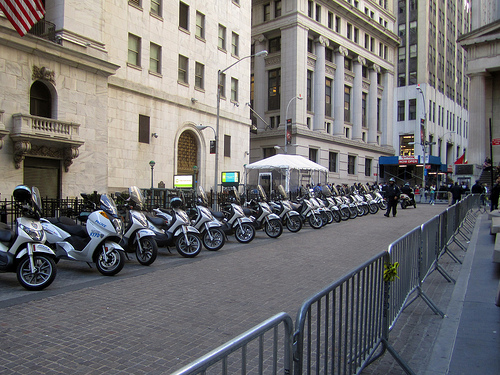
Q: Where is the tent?
A: Behind mopeds.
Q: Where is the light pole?
A: Behind the mopeds.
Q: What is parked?
A: Motorbikes.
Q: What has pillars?
A: Buildings.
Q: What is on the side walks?
A: Light posts.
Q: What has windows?
A: Buildings.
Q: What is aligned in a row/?
A: Motorcycles.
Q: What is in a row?
A: The motorbikes.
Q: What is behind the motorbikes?
A: A black metal fence.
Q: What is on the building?
A: A balcony.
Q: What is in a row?
A: Mopeds.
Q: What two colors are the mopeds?
A: Black and silver.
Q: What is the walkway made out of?
A: Bricks.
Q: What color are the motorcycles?
A: White.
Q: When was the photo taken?
A: Daytime.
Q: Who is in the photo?
A: A man.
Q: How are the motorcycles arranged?
A: In a straight line.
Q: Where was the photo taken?
A: On the street.